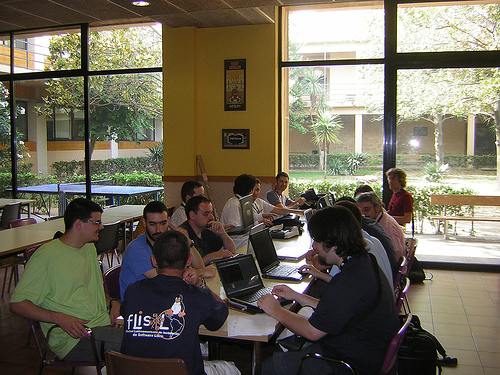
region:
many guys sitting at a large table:
[58, 161, 416, 370]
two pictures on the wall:
[206, 48, 263, 167]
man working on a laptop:
[206, 251, 286, 311]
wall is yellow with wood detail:
[166, 27, 271, 182]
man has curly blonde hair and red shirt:
[379, 160, 416, 225]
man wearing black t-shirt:
[129, 241, 222, 359]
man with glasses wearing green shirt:
[7, 196, 119, 352]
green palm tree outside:
[285, 71, 346, 179]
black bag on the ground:
[396, 311, 440, 367]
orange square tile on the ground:
[432, 276, 498, 365]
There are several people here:
[35, 105, 449, 355]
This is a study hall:
[9, 12, 497, 359]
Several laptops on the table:
[200, 170, 352, 341]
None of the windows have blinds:
[6, 34, 494, 244]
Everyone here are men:
[63, 147, 455, 334]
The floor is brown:
[386, 212, 491, 373]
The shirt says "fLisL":
[100, 272, 191, 337]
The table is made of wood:
[135, 157, 342, 358]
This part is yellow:
[170, 27, 298, 182]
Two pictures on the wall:
[192, 34, 264, 154]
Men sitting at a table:
[27, 167, 415, 369]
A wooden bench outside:
[425, 184, 497, 250]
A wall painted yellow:
[163, 24, 280, 186]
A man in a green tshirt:
[17, 195, 117, 351]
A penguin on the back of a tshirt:
[118, 269, 205, 369]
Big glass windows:
[2, 4, 498, 258]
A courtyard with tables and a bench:
[54, 139, 491, 235]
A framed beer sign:
[212, 123, 274, 168]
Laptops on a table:
[197, 189, 311, 324]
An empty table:
[1, 191, 161, 286]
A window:
[291, 9, 369, 67]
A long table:
[12, 224, 47, 244]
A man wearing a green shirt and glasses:
[47, 207, 108, 320]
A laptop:
[225, 260, 267, 302]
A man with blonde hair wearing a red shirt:
[387, 173, 410, 215]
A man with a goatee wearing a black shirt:
[185, 209, 217, 255]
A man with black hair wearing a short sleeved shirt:
[317, 221, 370, 353]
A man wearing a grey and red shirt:
[274, 174, 298, 214]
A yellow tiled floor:
[442, 283, 489, 350]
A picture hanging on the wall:
[214, 128, 261, 155]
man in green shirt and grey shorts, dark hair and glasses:
[9, 190, 122, 359]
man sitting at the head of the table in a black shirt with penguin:
[120, 227, 237, 373]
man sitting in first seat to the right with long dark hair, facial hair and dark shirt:
[250, 205, 397, 373]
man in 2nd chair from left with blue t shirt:
[121, 204, 208, 302]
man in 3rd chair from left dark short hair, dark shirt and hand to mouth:
[179, 194, 238, 256]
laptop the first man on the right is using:
[213, 250, 295, 309]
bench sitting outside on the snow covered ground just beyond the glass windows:
[425, 183, 496, 236]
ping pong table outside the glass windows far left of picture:
[13, 151, 160, 208]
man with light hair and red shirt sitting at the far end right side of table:
[377, 161, 414, 222]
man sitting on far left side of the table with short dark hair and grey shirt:
[268, 165, 304, 209]